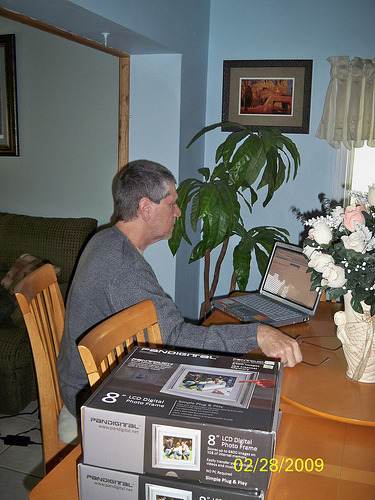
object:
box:
[76, 459, 265, 499]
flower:
[321, 262, 349, 288]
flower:
[340, 205, 365, 233]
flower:
[309, 217, 333, 246]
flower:
[340, 231, 367, 255]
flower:
[307, 250, 335, 273]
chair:
[77, 299, 164, 393]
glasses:
[277, 334, 342, 367]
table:
[27, 291, 375, 499]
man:
[56, 158, 302, 421]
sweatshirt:
[57, 225, 260, 420]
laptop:
[210, 241, 322, 328]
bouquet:
[302, 181, 374, 317]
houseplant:
[168, 122, 301, 325]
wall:
[198, 0, 374, 319]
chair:
[14, 263, 78, 476]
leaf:
[254, 244, 269, 278]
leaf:
[262, 225, 290, 236]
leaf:
[263, 147, 277, 209]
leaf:
[223, 129, 251, 168]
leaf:
[185, 121, 253, 150]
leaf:
[168, 178, 205, 258]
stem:
[204, 249, 212, 320]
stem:
[199, 238, 229, 323]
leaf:
[196, 181, 240, 252]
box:
[80, 345, 283, 492]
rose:
[302, 244, 315, 260]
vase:
[334, 289, 375, 384]